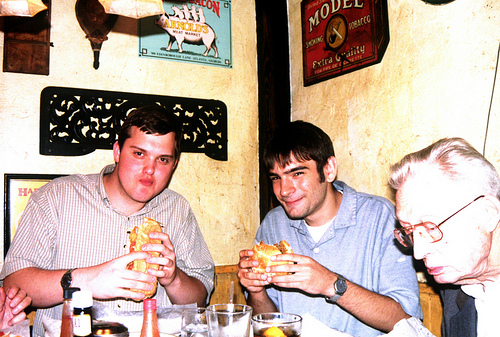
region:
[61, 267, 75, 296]
Man's black watch on left hand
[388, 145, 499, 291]
elderly man with glasses looking down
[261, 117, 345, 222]
guy grinning at the camera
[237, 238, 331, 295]
man holding a sandwich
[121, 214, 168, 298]
Man eating a sandwich on haogie bread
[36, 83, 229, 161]
Black decoration hanging on the wall.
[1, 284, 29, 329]
Person's fingers curled up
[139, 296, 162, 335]
Top of the hot sauce bottle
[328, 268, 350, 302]
Guy wearing silver-blue watch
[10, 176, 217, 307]
White and blue checkered button down shirt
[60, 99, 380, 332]
Two young men in the foreground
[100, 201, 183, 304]
Man is holding a sub sandwich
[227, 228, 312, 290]
Man is holding a burger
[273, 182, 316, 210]
Young man is smiling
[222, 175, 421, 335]
Man is wearing a blue shirt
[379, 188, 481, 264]
Older man is wearing eyeglasses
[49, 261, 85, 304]
Man is wearing a wristwatch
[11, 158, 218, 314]
Man is wearing a button up shirt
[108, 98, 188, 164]
Man has short dark colored hair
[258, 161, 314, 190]
Man has brown colored eyes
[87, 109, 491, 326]
three men in restaurant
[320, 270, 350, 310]
watch on man's wrist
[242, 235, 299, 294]
hamburger in two hands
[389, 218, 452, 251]
glasses on man's face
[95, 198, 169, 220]
open collar on shirt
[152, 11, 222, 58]
pig on wall plaque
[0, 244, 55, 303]
short sleeve on shirt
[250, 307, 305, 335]
glass full of beer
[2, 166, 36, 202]
black frame on picture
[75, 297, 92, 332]
bottle of sauce on table.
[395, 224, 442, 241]
glasses on man's face.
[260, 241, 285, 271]
burger in man's hand.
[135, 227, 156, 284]
sandwich in man's hand.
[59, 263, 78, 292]
watch on man's wrist.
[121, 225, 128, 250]
buttons on man's shirt.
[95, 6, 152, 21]
light on the wall.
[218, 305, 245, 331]
glass on the table.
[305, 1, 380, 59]
poster on the wall.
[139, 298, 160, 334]
bottle on the table.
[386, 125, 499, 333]
An old man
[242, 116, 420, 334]
A man in a blue shirt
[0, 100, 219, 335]
A man eating a sandwich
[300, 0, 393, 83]
A model sign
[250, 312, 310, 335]
A drinking glass with a lemon in it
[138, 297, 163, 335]
A bottle of hot sauce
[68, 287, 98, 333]
A bottle of steak sauce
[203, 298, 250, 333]
An empty drinking glass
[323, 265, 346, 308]
A watch on a man in a blue shirt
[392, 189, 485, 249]
Glasses on an old man